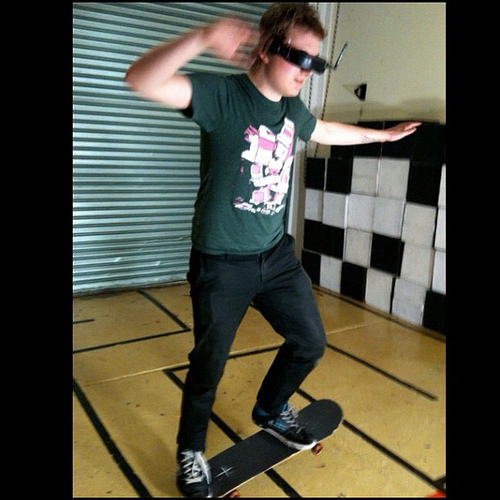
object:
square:
[320, 188, 345, 228]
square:
[304, 188, 322, 222]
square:
[349, 157, 380, 198]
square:
[375, 159, 410, 204]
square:
[347, 191, 378, 233]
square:
[369, 195, 406, 238]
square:
[341, 229, 374, 268]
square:
[318, 255, 343, 293]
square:
[392, 276, 427, 321]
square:
[391, 279, 426, 328]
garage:
[81, 6, 443, 500]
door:
[73, 4, 295, 299]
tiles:
[298, 121, 445, 326]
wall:
[303, 18, 445, 338]